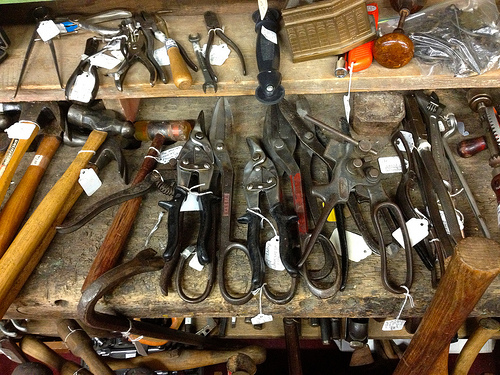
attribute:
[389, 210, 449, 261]
tag — little, white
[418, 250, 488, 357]
handle — wooden, rounded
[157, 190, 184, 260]
handle — black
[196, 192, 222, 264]
handle — black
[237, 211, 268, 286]
handle — black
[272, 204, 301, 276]
handle — black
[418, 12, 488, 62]
bag — plastic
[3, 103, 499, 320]
shelf — wooden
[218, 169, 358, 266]
tools — lower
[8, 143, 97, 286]
handle — wooden, brown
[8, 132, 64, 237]
handle — wooden, brown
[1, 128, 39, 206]
handle — wooden, brown